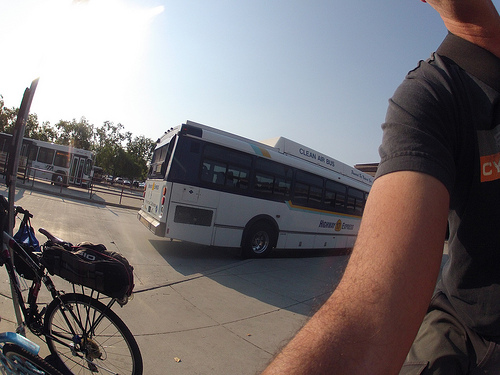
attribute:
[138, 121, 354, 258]
bus — white, passenger bus, large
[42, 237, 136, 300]
bag — long, black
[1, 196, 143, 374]
bicycle — leaning, parked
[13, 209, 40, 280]
bike helmet — blue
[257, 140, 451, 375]
arm — bare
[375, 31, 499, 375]
shirt — black, short sleeve, gray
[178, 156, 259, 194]
windows — black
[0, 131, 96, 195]
bus — white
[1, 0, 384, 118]
sky — blue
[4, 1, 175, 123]
clouds — white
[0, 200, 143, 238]
road — cement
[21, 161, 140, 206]
railing — metal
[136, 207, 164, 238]
bumper — white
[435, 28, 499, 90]
strap — brown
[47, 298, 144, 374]
spokes — metal, black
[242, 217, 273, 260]
wheel — black